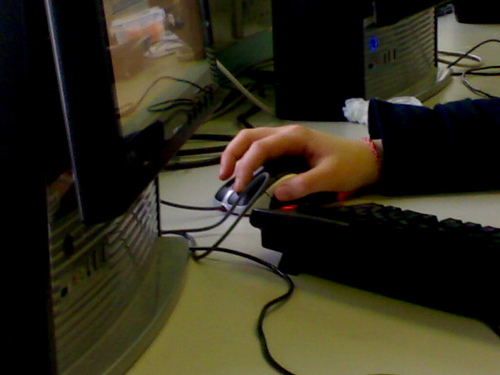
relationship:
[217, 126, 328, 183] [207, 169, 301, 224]
hand on mouse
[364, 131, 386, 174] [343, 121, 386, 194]
bracelet on wrist